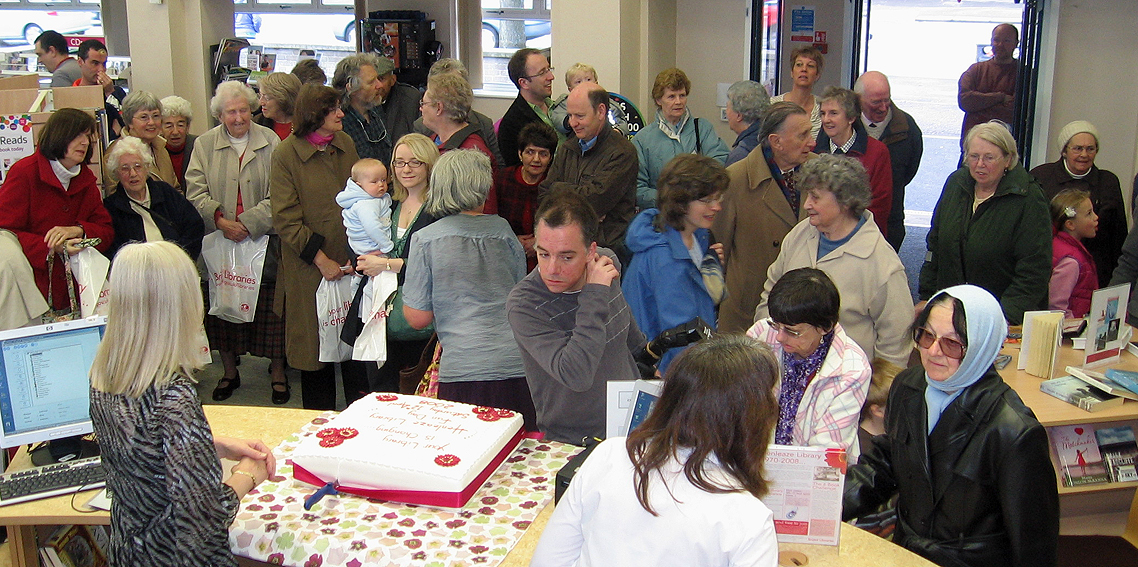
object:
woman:
[88, 239, 237, 565]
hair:
[89, 239, 205, 399]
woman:
[4, 107, 114, 309]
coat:
[2, 150, 114, 310]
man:
[536, 80, 639, 247]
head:
[565, 82, 609, 141]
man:
[959, 24, 1029, 154]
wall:
[1049, 0, 1138, 220]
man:
[508, 206, 645, 439]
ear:
[587, 242, 598, 263]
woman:
[529, 332, 790, 567]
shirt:
[536, 435, 778, 566]